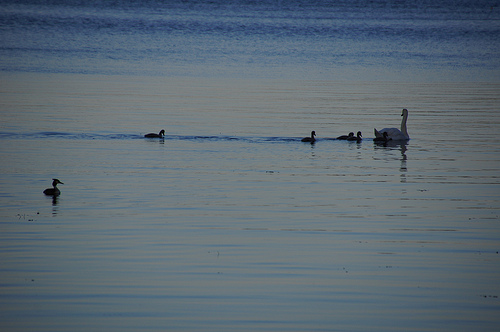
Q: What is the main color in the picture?
A: Blue.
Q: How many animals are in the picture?
A: Seven.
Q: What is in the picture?
A: Geese.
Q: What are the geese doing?
A: Swimming.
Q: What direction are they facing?
A: Right side.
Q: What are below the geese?
A: Water.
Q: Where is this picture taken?
A: In a sea.